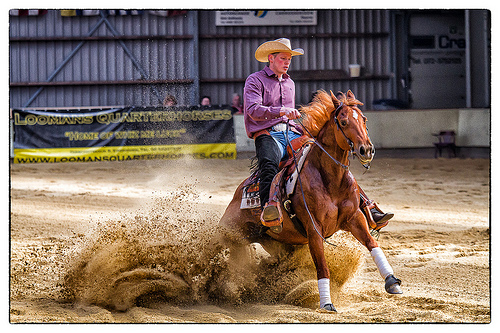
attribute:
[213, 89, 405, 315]
horse — brown, running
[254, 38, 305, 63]
cowboy hat — light brown